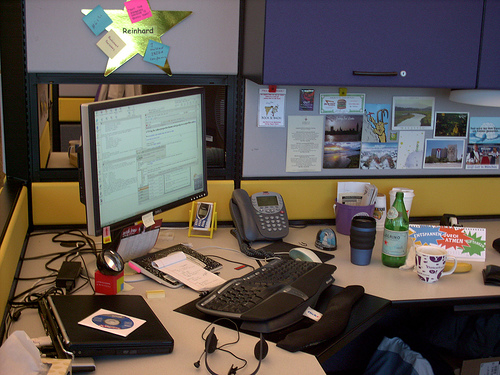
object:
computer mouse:
[94, 244, 125, 276]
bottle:
[381, 190, 409, 269]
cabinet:
[239, 0, 481, 89]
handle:
[352, 69, 400, 77]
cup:
[415, 246, 457, 284]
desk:
[1, 219, 499, 375]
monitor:
[76, 86, 208, 238]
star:
[80, 0, 193, 79]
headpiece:
[194, 316, 269, 374]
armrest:
[276, 284, 364, 354]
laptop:
[37, 290, 174, 356]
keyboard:
[194, 257, 338, 321]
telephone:
[228, 187, 291, 243]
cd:
[79, 309, 146, 338]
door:
[22, 0, 241, 75]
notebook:
[150, 251, 228, 293]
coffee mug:
[347, 214, 376, 265]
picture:
[323, 113, 364, 170]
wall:
[243, 78, 500, 179]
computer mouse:
[287, 246, 323, 265]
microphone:
[193, 359, 201, 370]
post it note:
[142, 210, 156, 229]